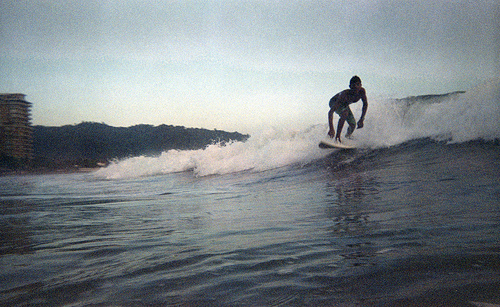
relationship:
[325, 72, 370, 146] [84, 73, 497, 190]
surfer on wave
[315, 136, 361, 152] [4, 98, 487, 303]
surfboard in water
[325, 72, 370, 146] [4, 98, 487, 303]
surfer in water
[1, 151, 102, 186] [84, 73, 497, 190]
coastline behind wave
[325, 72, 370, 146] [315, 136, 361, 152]
surfer on surfboard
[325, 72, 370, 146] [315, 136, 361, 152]
surfer riding surfboard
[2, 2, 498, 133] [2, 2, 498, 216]
sky in background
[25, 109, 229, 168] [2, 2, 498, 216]
mountain in background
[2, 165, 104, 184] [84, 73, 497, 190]
beach behind wave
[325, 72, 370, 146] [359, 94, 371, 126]
surfer has arm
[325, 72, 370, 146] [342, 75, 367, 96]
surfer has head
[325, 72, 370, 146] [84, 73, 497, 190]
surfer riding wave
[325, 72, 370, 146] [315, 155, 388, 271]
surfer cast shadow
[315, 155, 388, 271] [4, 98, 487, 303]
shadow on water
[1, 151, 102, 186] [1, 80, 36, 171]
coastline in front of building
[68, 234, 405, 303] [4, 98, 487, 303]
ripples in water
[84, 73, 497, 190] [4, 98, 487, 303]
wave in water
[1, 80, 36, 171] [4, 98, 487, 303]
building next to water